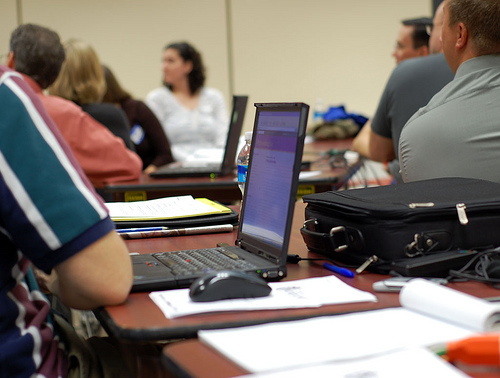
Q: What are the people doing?
A: Sitting.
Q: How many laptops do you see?
A: 2.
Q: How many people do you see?
A: 8.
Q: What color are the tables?
A: Brown.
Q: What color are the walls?
A: White.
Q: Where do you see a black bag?
A: Behind the closest laptop in the picture.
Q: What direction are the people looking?
A: To the left.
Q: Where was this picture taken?
A: At a conference.